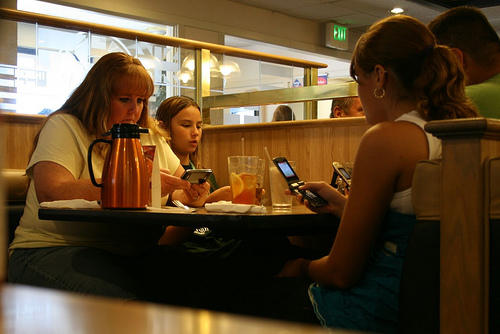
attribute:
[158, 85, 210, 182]
hair — long, blonde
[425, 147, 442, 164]
ground — illuminated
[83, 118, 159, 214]
pot — brass, black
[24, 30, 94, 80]
glass — frosted, patterned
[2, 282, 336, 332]
surface — glossy, tan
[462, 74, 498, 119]
shirt — lime green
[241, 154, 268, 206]
cup — plastic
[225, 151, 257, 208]
cup — plastic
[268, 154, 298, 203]
cup — plastic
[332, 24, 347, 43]
lettering — green